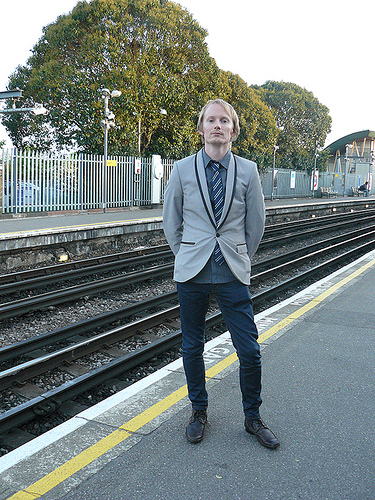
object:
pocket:
[236, 242, 249, 254]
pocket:
[179, 240, 195, 246]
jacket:
[161, 145, 266, 286]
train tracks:
[0, 228, 374, 433]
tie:
[210, 159, 223, 224]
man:
[160, 96, 280, 450]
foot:
[242, 416, 280, 449]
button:
[216, 231, 219, 236]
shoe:
[241, 411, 281, 449]